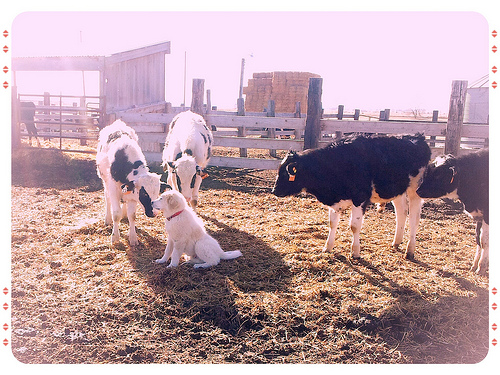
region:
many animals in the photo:
[54, 78, 476, 278]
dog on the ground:
[137, 158, 238, 263]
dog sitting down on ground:
[128, 181, 230, 274]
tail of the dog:
[216, 238, 244, 274]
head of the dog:
[148, 191, 193, 218]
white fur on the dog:
[172, 208, 207, 260]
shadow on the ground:
[156, 266, 247, 350]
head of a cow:
[247, 138, 313, 234]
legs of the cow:
[322, 206, 432, 271]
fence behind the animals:
[232, 105, 296, 164]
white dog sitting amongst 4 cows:
[146, 185, 242, 270]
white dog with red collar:
[148, 184, 242, 271]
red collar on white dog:
[163, 207, 189, 222]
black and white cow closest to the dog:
[91, 114, 173, 246]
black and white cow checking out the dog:
[156, 106, 212, 211]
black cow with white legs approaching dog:
[261, 128, 431, 270]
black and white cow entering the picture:
[411, 140, 491, 279]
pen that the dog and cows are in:
[11, 152, 490, 365]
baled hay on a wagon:
[244, 71, 320, 116]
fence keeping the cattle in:
[99, 104, 489, 189]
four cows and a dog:
[56, 89, 488, 296]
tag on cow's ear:
[278, 159, 305, 185]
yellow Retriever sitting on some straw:
[145, 188, 245, 275]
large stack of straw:
[237, 63, 319, 121]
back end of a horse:
[15, 89, 50, 154]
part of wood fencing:
[214, 108, 275, 173]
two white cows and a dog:
[90, 108, 252, 273]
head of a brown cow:
[416, 144, 473, 208]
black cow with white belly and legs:
[265, 131, 433, 262]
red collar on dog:
[162, 208, 188, 221]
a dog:
[138, 192, 250, 279]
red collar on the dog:
[170, 204, 187, 218]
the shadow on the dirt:
[173, 275, 255, 331]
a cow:
[250, 133, 422, 253]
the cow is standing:
[260, 145, 422, 256]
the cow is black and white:
[256, 137, 421, 252]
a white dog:
[149, 185, 245, 275]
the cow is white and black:
[89, 112, 157, 234]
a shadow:
[234, 230, 294, 287]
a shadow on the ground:
[22, 141, 79, 191]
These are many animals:
[104, 141, 394, 295]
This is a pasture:
[178, 162, 470, 372]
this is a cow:
[267, 132, 453, 277]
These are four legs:
[316, 209, 476, 238]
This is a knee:
[316, 211, 379, 235]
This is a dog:
[109, 207, 423, 372]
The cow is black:
[284, 137, 401, 219]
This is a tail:
[217, 236, 244, 256]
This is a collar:
[164, 203, 179, 224]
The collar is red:
[171, 207, 183, 222]